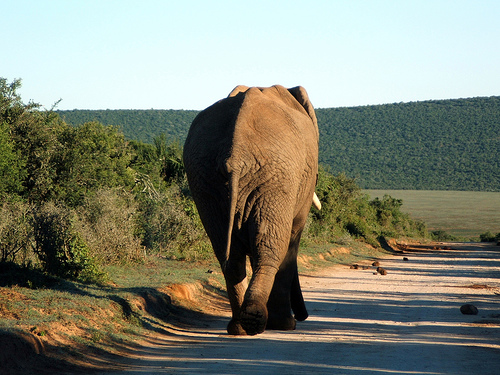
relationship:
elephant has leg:
[182, 83, 322, 333] [192, 208, 250, 314]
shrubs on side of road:
[24, 199, 109, 286] [391, 258, 453, 306]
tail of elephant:
[219, 177, 240, 277] [182, 83, 322, 333]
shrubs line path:
[24, 199, 109, 286] [10, 235, 499, 373]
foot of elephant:
[237, 298, 270, 339] [182, 83, 322, 333]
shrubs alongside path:
[24, 199, 109, 286] [63, 223, 499, 367]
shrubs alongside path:
[38, 112, 110, 300] [63, 223, 499, 367]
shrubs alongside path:
[318, 155, 404, 232] [63, 223, 499, 367]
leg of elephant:
[179, 179, 254, 343] [165, 73, 334, 345]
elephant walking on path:
[182, 83, 322, 333] [0, 241, 499, 375]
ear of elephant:
[290, 81, 326, 133] [173, 28, 391, 345]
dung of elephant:
[345, 259, 391, 276] [133, 32, 358, 344]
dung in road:
[345, 259, 391, 276] [103, 242, 492, 371]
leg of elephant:
[244, 201, 291, 299] [179, 81, 332, 339]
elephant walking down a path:
[182, 83, 322, 333] [74, 243, 498, 371]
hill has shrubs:
[35, 95, 498, 188] [477, 166, 497, 182]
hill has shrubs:
[35, 95, 498, 188] [435, 139, 456, 156]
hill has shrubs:
[35, 95, 498, 188] [439, 110, 456, 125]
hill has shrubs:
[35, 95, 498, 188] [382, 139, 401, 165]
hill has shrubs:
[35, 95, 498, 188] [479, 101, 492, 110]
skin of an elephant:
[177, 82, 326, 338] [182, 83, 322, 333]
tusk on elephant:
[309, 189, 329, 208] [166, 69, 328, 331]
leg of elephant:
[244, 201, 291, 299] [182, 83, 322, 333]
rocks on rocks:
[378, 270, 383, 276] [347, 265, 358, 270]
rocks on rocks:
[378, 270, 383, 276] [372, 259, 377, 265]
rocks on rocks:
[378, 270, 383, 276] [370, 270, 376, 280]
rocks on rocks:
[378, 270, 383, 276] [362, 265, 367, 270]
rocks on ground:
[378, 270, 383, 276] [245, 248, 493, 372]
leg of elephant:
[244, 209, 291, 331] [182, 83, 322, 333]